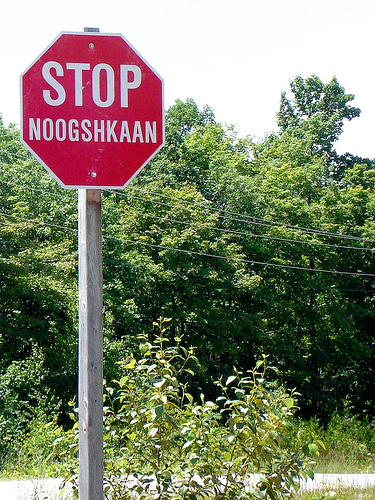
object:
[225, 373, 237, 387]
leaves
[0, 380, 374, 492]
side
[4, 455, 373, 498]
road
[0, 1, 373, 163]
sky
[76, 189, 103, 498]
pole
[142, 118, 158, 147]
letters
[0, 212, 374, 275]
lines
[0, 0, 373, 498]
picture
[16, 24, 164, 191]
sign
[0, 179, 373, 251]
wires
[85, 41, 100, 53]
screw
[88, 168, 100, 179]
screw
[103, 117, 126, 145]
letter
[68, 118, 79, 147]
g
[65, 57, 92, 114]
letter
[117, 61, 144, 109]
letter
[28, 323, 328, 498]
greenery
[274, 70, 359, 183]
trees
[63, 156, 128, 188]
bottom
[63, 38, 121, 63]
top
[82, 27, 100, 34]
tip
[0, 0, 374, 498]
background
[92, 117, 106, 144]
letter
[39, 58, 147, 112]
stop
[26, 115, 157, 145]
word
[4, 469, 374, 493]
roadway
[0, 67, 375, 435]
forest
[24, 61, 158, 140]
language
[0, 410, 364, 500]
weeds